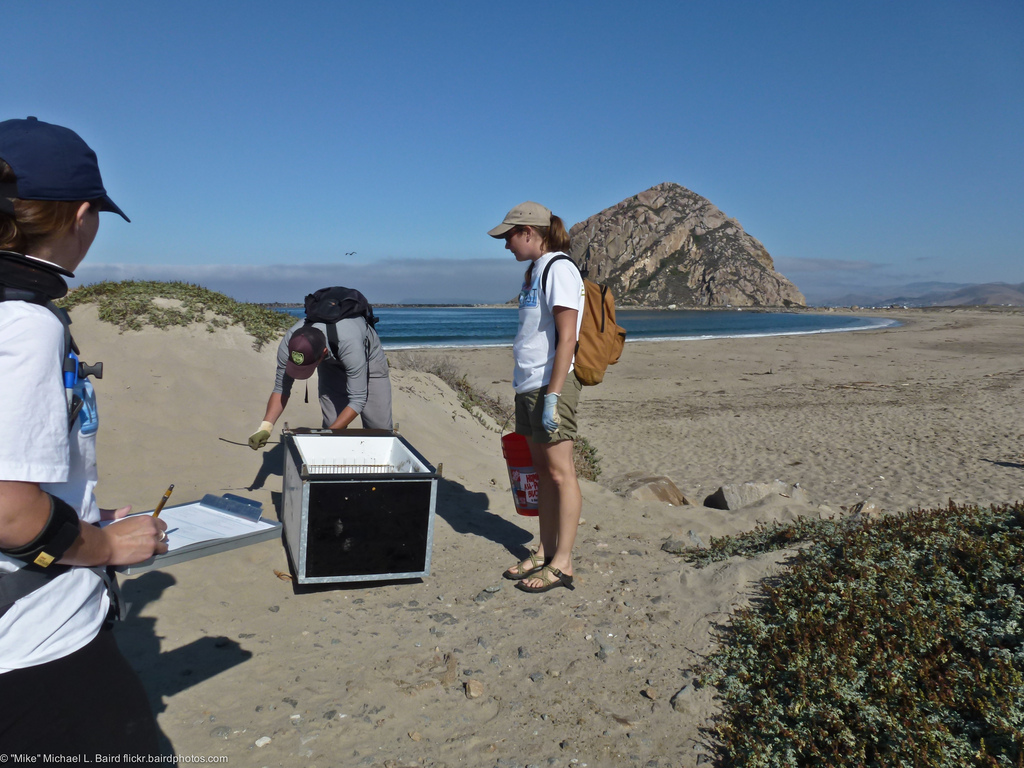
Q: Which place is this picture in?
A: It is at the beach.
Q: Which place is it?
A: It is a beach.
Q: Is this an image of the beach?
A: Yes, it is showing the beach.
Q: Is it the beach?
A: Yes, it is the beach.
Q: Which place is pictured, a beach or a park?
A: It is a beach.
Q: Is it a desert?
A: No, it is a beach.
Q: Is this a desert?
A: No, it is a beach.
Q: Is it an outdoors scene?
A: Yes, it is outdoors.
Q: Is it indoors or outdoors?
A: It is outdoors.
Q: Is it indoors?
A: No, it is outdoors.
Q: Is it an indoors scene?
A: No, it is outdoors.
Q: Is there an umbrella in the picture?
A: No, there are no umbrellas.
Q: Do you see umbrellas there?
A: No, there are no umbrellas.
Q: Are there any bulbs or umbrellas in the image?
A: No, there are no umbrellas or bulbs.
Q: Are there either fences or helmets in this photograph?
A: No, there are no fences or helmets.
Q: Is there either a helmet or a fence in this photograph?
A: No, there are no fences or helmets.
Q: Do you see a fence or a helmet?
A: No, there are no fences or helmets.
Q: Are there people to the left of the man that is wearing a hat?
A: Yes, there is a person to the left of the man.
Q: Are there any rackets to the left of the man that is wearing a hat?
A: No, there is a person to the left of the man.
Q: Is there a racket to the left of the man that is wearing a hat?
A: No, there is a person to the left of the man.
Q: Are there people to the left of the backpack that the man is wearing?
A: Yes, there is a person to the left of the backpack.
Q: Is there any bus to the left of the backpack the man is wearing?
A: No, there is a person to the left of the backpack.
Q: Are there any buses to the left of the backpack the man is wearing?
A: No, there is a person to the left of the backpack.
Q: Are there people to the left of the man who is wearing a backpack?
A: Yes, there is a person to the left of the man.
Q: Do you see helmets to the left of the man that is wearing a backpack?
A: No, there is a person to the left of the man.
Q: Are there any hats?
A: Yes, there is a hat.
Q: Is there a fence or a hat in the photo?
A: Yes, there is a hat.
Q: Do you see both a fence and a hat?
A: No, there is a hat but no fences.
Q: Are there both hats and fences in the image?
A: No, there is a hat but no fences.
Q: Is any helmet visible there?
A: No, there are no helmets.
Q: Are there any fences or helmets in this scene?
A: No, there are no helmets or fences.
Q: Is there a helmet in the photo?
A: No, there are no helmets.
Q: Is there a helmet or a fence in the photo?
A: No, there are no helmets or fences.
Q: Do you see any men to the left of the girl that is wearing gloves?
A: Yes, there is a man to the left of the girl.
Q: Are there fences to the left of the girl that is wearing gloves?
A: No, there is a man to the left of the girl.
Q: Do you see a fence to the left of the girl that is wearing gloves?
A: No, there is a man to the left of the girl.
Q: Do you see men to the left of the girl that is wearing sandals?
A: Yes, there is a man to the left of the girl.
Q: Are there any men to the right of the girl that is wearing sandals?
A: No, the man is to the left of the girl.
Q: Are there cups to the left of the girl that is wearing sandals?
A: No, there is a man to the left of the girl.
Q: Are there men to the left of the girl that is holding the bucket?
A: Yes, there is a man to the left of the girl.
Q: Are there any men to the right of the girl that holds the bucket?
A: No, the man is to the left of the girl.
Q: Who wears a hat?
A: The man wears a hat.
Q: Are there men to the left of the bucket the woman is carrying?
A: Yes, there is a man to the left of the bucket.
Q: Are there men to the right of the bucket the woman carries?
A: No, the man is to the left of the bucket.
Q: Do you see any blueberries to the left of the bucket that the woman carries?
A: No, there is a man to the left of the bucket.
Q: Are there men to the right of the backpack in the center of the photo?
A: No, the man is to the left of the backpack.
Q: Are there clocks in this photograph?
A: No, there are no clocks.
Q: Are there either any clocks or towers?
A: No, there are no clocks or towers.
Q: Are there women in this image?
A: Yes, there is a woman.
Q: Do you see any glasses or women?
A: Yes, there is a woman.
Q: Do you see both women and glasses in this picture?
A: Yes, there are both a woman and glasses.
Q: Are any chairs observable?
A: No, there are no chairs.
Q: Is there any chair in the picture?
A: No, there are no chairs.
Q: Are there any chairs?
A: No, there are no chairs.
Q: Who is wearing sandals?
A: The woman is wearing sandals.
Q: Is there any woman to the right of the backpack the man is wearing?
A: Yes, there is a woman to the right of the backpack.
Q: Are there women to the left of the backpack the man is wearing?
A: No, the woman is to the right of the backpack.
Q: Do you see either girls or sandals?
A: Yes, there are sandals.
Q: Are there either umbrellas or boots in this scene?
A: No, there are no umbrellas or boots.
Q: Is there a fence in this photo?
A: No, there are no fences.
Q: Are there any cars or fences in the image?
A: No, there are no fences or cars.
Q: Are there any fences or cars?
A: No, there are no fences or cars.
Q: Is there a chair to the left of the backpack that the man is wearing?
A: No, there is a person to the left of the backpack.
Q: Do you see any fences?
A: No, there are no fences.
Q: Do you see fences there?
A: No, there are no fences.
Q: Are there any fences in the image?
A: No, there are no fences.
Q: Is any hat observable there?
A: Yes, there is a hat.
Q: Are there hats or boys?
A: Yes, there is a hat.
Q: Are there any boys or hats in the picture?
A: Yes, there is a hat.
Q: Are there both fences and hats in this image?
A: No, there is a hat but no fences.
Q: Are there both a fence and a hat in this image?
A: No, there is a hat but no fences.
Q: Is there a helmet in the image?
A: No, there are no helmets.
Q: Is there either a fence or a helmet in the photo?
A: No, there are no helmets or fences.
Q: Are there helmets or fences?
A: No, there are no helmets or fences.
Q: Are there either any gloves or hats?
A: Yes, there is a hat.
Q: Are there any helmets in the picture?
A: No, there are no helmets.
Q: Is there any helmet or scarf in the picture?
A: No, there are no helmets or scarves.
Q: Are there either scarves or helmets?
A: No, there are no helmets or scarves.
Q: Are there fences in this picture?
A: No, there are no fences.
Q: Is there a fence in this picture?
A: No, there are no fences.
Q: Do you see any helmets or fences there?
A: No, there are no fences or helmets.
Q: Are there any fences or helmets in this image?
A: No, there are no fences or helmets.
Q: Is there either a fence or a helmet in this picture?
A: No, there are no fences or helmets.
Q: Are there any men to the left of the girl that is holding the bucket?
A: Yes, there is a man to the left of the girl.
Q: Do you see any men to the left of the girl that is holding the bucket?
A: Yes, there is a man to the left of the girl.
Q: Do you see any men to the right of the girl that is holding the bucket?
A: No, the man is to the left of the girl.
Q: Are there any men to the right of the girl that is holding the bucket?
A: No, the man is to the left of the girl.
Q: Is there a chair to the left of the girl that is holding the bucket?
A: No, there is a man to the left of the girl.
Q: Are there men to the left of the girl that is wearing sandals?
A: Yes, there is a man to the left of the girl.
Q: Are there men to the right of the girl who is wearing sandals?
A: No, the man is to the left of the girl.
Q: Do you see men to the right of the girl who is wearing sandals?
A: No, the man is to the left of the girl.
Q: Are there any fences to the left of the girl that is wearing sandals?
A: No, there is a man to the left of the girl.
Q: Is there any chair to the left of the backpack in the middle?
A: No, there is a man to the left of the backpack.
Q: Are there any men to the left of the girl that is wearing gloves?
A: Yes, there is a man to the left of the girl.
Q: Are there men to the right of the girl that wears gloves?
A: No, the man is to the left of the girl.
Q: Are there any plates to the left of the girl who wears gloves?
A: No, there is a man to the left of the girl.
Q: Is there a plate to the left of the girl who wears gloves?
A: No, there is a man to the left of the girl.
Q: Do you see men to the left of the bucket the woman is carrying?
A: Yes, there is a man to the left of the bucket.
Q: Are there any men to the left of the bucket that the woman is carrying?
A: Yes, there is a man to the left of the bucket.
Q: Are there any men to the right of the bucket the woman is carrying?
A: No, the man is to the left of the bucket.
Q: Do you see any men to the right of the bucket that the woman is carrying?
A: No, the man is to the left of the bucket.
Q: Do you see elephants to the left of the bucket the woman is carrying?
A: No, there is a man to the left of the bucket.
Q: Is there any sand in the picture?
A: Yes, there is sand.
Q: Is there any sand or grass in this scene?
A: Yes, there is sand.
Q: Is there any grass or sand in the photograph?
A: Yes, there is sand.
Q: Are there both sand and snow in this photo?
A: No, there is sand but no snow.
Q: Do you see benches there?
A: No, there are no benches.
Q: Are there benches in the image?
A: No, there are no benches.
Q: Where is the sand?
A: The sand is on the beach.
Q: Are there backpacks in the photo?
A: Yes, there is a backpack.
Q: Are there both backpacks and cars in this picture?
A: No, there is a backpack but no cars.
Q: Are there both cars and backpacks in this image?
A: No, there is a backpack but no cars.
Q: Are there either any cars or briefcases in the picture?
A: No, there are no cars or briefcases.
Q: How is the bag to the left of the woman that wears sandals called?
A: The bag is a backpack.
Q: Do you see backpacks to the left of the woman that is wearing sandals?
A: Yes, there is a backpack to the left of the woman.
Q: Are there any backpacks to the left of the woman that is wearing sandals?
A: Yes, there is a backpack to the left of the woman.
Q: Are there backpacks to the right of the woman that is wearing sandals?
A: No, the backpack is to the left of the woman.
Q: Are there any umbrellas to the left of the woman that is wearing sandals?
A: No, there is a backpack to the left of the woman.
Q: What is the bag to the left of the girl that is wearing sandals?
A: The bag is a backpack.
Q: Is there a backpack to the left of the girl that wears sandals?
A: Yes, there is a backpack to the left of the girl.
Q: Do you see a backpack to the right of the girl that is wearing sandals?
A: No, the backpack is to the left of the girl.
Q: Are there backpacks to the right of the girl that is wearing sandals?
A: No, the backpack is to the left of the girl.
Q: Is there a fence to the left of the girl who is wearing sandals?
A: No, there is a backpack to the left of the girl.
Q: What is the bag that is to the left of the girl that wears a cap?
A: The bag is a backpack.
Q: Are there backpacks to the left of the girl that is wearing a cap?
A: Yes, there is a backpack to the left of the girl.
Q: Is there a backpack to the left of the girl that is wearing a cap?
A: Yes, there is a backpack to the left of the girl.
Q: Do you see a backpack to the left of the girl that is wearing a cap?
A: Yes, there is a backpack to the left of the girl.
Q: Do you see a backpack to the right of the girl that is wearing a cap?
A: No, the backpack is to the left of the girl.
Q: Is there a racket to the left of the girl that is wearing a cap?
A: No, there is a backpack to the left of the girl.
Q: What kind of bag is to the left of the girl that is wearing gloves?
A: The bag is a backpack.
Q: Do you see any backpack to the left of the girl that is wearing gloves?
A: Yes, there is a backpack to the left of the girl.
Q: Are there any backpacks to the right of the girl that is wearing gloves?
A: No, the backpack is to the left of the girl.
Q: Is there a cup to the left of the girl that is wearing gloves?
A: No, there is a backpack to the left of the girl.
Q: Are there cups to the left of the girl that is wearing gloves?
A: No, there is a backpack to the left of the girl.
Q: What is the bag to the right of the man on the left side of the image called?
A: The bag is a backpack.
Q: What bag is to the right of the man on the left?
A: The bag is a backpack.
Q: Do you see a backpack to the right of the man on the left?
A: Yes, there is a backpack to the right of the man.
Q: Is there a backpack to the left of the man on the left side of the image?
A: No, the backpack is to the right of the man.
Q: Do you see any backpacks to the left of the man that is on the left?
A: No, the backpack is to the right of the man.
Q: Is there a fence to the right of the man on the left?
A: No, there is a backpack to the right of the man.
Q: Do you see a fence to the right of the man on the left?
A: No, there is a backpack to the right of the man.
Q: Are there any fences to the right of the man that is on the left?
A: No, there is a backpack to the right of the man.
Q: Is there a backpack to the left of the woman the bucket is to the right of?
A: Yes, there is a backpack to the left of the woman.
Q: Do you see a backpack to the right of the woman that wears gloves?
A: No, the backpack is to the left of the woman.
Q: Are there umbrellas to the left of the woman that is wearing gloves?
A: No, there is a backpack to the left of the woman.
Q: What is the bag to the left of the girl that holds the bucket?
A: The bag is a backpack.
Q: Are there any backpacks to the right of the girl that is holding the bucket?
A: No, the backpack is to the left of the girl.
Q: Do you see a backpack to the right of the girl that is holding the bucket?
A: No, the backpack is to the left of the girl.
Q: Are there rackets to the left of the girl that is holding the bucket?
A: No, there is a backpack to the left of the girl.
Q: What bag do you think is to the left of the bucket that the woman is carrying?
A: The bag is a backpack.